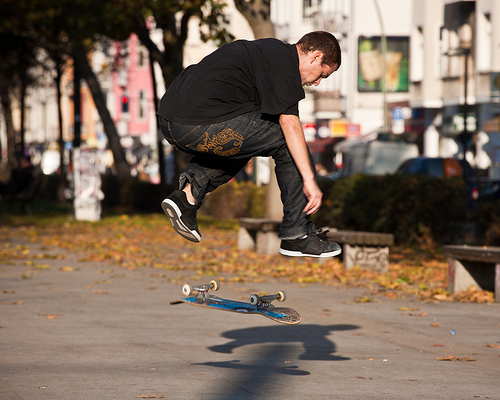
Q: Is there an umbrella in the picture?
A: No, there are no umbrellas.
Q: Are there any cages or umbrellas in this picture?
A: No, there are no umbrellas or cages.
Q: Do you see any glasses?
A: No, there are no glasses.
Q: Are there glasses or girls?
A: No, there are no glasses or girls.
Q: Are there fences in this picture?
A: No, there are no fences.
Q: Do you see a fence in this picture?
A: No, there are no fences.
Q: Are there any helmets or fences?
A: No, there are no fences or helmets.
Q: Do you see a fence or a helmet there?
A: No, there are no fences or helmets.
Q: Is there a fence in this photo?
A: No, there are no fences.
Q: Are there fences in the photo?
A: No, there are no fences.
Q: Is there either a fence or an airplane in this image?
A: No, there are no fences or airplanes.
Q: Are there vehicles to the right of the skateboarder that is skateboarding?
A: Yes, there is a vehicle to the right of the skateboarder.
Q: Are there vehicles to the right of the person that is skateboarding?
A: Yes, there is a vehicle to the right of the skateboarder.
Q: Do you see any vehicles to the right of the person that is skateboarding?
A: Yes, there is a vehicle to the right of the skateboarder.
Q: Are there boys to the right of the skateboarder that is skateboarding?
A: No, there is a vehicle to the right of the skateboarder.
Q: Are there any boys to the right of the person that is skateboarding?
A: No, there is a vehicle to the right of the skateboarder.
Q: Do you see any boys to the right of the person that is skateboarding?
A: No, there is a vehicle to the right of the skateboarder.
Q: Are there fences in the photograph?
A: No, there are no fences.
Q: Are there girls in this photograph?
A: No, there are no girls.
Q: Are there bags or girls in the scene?
A: No, there are no girls or bags.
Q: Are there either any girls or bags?
A: No, there are no girls or bags.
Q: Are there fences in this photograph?
A: No, there are no fences.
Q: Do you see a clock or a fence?
A: No, there are no fences or clocks.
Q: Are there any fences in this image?
A: No, there are no fences.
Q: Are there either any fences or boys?
A: No, there are no fences or boys.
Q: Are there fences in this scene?
A: No, there are no fences.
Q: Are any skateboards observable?
A: Yes, there is a skateboard.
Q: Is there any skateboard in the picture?
A: Yes, there is a skateboard.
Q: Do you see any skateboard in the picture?
A: Yes, there is a skateboard.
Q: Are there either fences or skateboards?
A: Yes, there is a skateboard.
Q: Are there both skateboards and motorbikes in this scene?
A: No, there is a skateboard but no motorcycles.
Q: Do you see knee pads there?
A: No, there are no knee pads.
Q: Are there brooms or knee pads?
A: No, there are no knee pads or brooms.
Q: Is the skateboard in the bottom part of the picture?
A: Yes, the skateboard is in the bottom of the image.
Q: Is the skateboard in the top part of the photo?
A: No, the skateboard is in the bottom of the image.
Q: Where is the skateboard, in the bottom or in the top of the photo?
A: The skateboard is in the bottom of the image.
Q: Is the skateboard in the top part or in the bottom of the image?
A: The skateboard is in the bottom of the image.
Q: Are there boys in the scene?
A: No, there are no boys.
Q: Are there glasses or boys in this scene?
A: No, there are no boys or glasses.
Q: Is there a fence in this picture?
A: No, there are no fences.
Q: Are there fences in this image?
A: No, there are no fences.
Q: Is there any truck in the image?
A: Yes, there is a truck.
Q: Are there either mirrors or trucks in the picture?
A: Yes, there is a truck.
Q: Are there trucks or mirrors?
A: Yes, there is a truck.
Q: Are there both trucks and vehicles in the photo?
A: Yes, there are both a truck and vehicles.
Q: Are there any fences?
A: No, there are no fences.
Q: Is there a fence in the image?
A: No, there are no fences.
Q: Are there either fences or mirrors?
A: No, there are no fences or mirrors.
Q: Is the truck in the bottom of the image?
A: Yes, the truck is in the bottom of the image.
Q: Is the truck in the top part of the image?
A: No, the truck is in the bottom of the image.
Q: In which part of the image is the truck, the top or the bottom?
A: The truck is in the bottom of the image.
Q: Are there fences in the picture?
A: No, there are no fences.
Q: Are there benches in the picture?
A: Yes, there is a bench.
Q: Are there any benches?
A: Yes, there is a bench.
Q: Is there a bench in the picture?
A: Yes, there is a bench.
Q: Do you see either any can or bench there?
A: Yes, there is a bench.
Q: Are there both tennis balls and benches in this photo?
A: No, there is a bench but no tennis balls.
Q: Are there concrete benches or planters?
A: Yes, there is a concrete bench.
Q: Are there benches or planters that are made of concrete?
A: Yes, the bench is made of concrete.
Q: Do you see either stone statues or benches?
A: Yes, there is a stone bench.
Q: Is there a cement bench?
A: Yes, there is a bench that is made of cement.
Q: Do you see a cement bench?
A: Yes, there is a bench that is made of cement.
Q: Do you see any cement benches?
A: Yes, there is a bench that is made of cement.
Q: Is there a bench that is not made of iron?
A: Yes, there is a bench that is made of concrete.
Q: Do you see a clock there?
A: No, there are no clocks.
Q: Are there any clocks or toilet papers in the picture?
A: No, there are no clocks or toilet papers.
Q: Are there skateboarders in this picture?
A: Yes, there is a skateboarder.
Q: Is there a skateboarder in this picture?
A: Yes, there is a skateboarder.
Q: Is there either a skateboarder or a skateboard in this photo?
A: Yes, there is a skateboarder.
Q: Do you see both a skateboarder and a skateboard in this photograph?
A: Yes, there are both a skateboarder and a skateboard.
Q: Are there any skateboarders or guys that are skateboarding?
A: Yes, the skateboarder is skateboarding.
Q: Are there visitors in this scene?
A: No, there are no visitors.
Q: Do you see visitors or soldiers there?
A: No, there are no visitors or soldiers.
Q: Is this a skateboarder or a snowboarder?
A: This is a skateboarder.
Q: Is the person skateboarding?
A: Yes, the skateboarder is skateboarding.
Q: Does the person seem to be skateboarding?
A: Yes, the skateboarder is skateboarding.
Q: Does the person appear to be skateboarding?
A: Yes, the skateboarder is skateboarding.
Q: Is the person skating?
A: No, the skateboarder is skateboarding.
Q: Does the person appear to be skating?
A: No, the skateboarder is skateboarding.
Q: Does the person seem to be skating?
A: No, the skateboarder is skateboarding.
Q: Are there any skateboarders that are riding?
A: No, there is a skateboarder but he is skateboarding.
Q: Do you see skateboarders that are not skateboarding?
A: No, there is a skateboarder but he is skateboarding.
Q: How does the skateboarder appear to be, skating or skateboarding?
A: The skateboarder is skateboarding.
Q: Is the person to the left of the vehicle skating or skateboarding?
A: The skateboarder is skateboarding.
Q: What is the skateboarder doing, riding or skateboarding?
A: The skateboarder is skateboarding.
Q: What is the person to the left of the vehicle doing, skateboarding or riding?
A: The skateboarder is skateboarding.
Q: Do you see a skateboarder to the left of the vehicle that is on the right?
A: Yes, there is a skateboarder to the left of the vehicle.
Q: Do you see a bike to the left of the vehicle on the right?
A: No, there is a skateboarder to the left of the vehicle.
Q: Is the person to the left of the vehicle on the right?
A: Yes, the skateboarder is to the left of the vehicle.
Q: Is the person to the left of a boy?
A: No, the skateboarder is to the left of the vehicle.